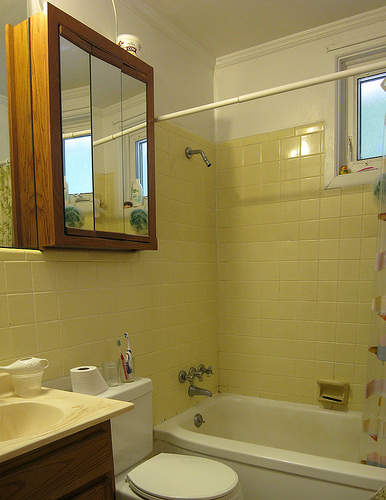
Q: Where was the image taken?
A: It was taken at the bathroom.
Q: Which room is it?
A: It is a bathroom.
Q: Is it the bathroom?
A: Yes, it is the bathroom.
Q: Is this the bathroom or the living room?
A: It is the bathroom.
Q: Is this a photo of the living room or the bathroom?
A: It is showing the bathroom.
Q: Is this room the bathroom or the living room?
A: It is the bathroom.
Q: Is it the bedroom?
A: No, it is the bathroom.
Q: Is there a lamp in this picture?
A: No, there are no lamps.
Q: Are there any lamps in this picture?
A: No, there are no lamps.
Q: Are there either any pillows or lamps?
A: No, there are no lamps or pillows.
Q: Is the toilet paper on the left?
A: Yes, the toilet paper is on the left of the image.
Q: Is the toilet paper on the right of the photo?
A: No, the toilet paper is on the left of the image.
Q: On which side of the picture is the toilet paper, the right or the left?
A: The toilet paper is on the left of the image.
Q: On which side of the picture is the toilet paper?
A: The toilet paper is on the left of the image.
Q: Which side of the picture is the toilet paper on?
A: The toilet paper is on the left of the image.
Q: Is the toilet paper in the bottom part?
A: Yes, the toilet paper is in the bottom of the image.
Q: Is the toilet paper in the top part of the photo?
A: No, the toilet paper is in the bottom of the image.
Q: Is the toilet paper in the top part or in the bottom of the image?
A: The toilet paper is in the bottom of the image.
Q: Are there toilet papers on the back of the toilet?
A: Yes, there is a toilet paper on the back of the toilet.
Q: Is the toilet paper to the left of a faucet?
A: Yes, the toilet paper is to the left of a faucet.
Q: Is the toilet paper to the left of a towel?
A: No, the toilet paper is to the left of a faucet.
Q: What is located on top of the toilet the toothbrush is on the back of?
A: The toilet paper is on top of the toilet.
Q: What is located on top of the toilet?
A: The toilet paper is on top of the toilet.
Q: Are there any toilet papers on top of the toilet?
A: Yes, there is a toilet paper on top of the toilet.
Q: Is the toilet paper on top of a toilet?
A: Yes, the toilet paper is on top of a toilet.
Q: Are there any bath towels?
A: No, there are no bath towels.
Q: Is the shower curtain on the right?
A: Yes, the shower curtain is on the right of the image.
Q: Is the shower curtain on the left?
A: No, the shower curtain is on the right of the image.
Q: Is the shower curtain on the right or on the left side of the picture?
A: The shower curtain is on the right of the image.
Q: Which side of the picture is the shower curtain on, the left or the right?
A: The shower curtain is on the right of the image.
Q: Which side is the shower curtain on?
A: The shower curtain is on the right of the image.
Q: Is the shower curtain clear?
A: Yes, the shower curtain is clear.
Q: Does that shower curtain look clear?
A: Yes, the shower curtain is clear.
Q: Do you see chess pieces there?
A: No, there are no chess pieces.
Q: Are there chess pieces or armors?
A: No, there are no chess pieces or armors.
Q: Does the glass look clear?
A: Yes, the glass is clear.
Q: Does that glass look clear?
A: Yes, the glass is clear.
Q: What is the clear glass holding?
A: The glass is holding the toothbrush.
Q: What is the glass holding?
A: The glass is holding the toothbrush.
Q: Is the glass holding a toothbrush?
A: Yes, the glass is holding a toothbrush.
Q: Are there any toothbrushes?
A: Yes, there is a toothbrush.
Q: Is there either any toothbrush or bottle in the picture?
A: Yes, there is a toothbrush.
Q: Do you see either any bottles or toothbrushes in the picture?
A: Yes, there is a toothbrush.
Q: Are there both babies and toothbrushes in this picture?
A: No, there is a toothbrush but no babies.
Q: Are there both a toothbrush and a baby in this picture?
A: No, there is a toothbrush but no babies.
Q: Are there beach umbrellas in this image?
A: No, there are no beach umbrellas.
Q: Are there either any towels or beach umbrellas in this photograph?
A: No, there are no beach umbrellas or towels.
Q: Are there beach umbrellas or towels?
A: No, there are no beach umbrellas or towels.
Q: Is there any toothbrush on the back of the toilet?
A: Yes, there is a toothbrush on the back of the toilet.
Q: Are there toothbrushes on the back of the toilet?
A: Yes, there is a toothbrush on the back of the toilet.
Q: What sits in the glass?
A: The toothbrush sits in the glass.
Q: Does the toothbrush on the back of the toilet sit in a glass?
A: Yes, the toothbrush sits in a glass.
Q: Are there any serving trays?
A: No, there are no serving trays.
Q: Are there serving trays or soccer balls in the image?
A: No, there are no serving trays or soccer balls.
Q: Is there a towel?
A: No, there are no towels.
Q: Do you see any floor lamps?
A: No, there are no floor lamps.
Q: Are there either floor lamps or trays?
A: No, there are no floor lamps or trays.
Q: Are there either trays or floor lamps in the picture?
A: No, there are no floor lamps or trays.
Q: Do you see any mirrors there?
A: Yes, there is a mirror.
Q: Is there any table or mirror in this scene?
A: Yes, there is a mirror.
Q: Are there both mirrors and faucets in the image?
A: Yes, there are both a mirror and a faucet.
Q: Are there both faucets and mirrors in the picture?
A: Yes, there are both a mirror and a faucet.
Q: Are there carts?
A: No, there are no carts.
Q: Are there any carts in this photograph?
A: No, there are no carts.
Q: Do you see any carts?
A: No, there are no carts.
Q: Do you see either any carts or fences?
A: No, there are no carts or fences.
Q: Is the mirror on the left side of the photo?
A: Yes, the mirror is on the left of the image.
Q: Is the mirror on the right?
A: No, the mirror is on the left of the image.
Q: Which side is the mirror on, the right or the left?
A: The mirror is on the left of the image.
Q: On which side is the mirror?
A: The mirror is on the left of the image.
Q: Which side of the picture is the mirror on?
A: The mirror is on the left of the image.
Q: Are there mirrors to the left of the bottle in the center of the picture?
A: Yes, there is a mirror to the left of the bottle.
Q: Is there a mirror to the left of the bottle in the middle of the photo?
A: Yes, there is a mirror to the left of the bottle.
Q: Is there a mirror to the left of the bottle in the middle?
A: Yes, there is a mirror to the left of the bottle.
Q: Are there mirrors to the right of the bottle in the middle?
A: No, the mirror is to the left of the bottle.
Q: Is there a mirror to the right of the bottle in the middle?
A: No, the mirror is to the left of the bottle.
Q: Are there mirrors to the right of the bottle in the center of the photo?
A: No, the mirror is to the left of the bottle.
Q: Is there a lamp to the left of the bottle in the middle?
A: No, there is a mirror to the left of the bottle.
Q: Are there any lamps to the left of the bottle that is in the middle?
A: No, there is a mirror to the left of the bottle.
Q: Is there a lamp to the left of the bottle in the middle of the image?
A: No, there is a mirror to the left of the bottle.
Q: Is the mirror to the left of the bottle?
A: Yes, the mirror is to the left of the bottle.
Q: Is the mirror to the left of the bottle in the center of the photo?
A: Yes, the mirror is to the left of the bottle.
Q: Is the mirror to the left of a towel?
A: No, the mirror is to the left of the bottle.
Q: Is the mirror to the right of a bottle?
A: No, the mirror is to the left of a bottle.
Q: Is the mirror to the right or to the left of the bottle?
A: The mirror is to the left of the bottle.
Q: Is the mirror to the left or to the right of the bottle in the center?
A: The mirror is to the left of the bottle.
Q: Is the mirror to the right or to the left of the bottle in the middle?
A: The mirror is to the left of the bottle.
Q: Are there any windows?
A: Yes, there is a window.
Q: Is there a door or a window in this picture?
A: Yes, there is a window.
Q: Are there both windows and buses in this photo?
A: No, there is a window but no buses.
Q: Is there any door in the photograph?
A: No, there are no doors.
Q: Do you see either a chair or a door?
A: No, there are no doors or chairs.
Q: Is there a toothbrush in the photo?
A: Yes, there is a toothbrush.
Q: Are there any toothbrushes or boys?
A: Yes, there is a toothbrush.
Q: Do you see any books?
A: No, there are no books.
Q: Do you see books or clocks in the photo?
A: No, there are no books or clocks.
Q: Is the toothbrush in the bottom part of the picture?
A: Yes, the toothbrush is in the bottom of the image.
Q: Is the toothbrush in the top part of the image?
A: No, the toothbrush is in the bottom of the image.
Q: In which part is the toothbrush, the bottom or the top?
A: The toothbrush is in the bottom of the image.